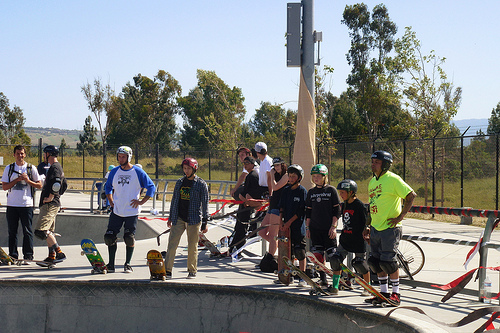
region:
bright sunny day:
[12, 7, 499, 98]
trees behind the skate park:
[7, 62, 497, 152]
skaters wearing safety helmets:
[121, 130, 431, 190]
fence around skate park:
[422, 137, 492, 195]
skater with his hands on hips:
[97, 157, 153, 227]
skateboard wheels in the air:
[85, 242, 387, 305]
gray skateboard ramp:
[23, 273, 333, 329]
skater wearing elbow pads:
[51, 175, 66, 196]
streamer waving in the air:
[425, 238, 495, 329]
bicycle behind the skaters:
[391, 232, 436, 292]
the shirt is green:
[367, 157, 417, 245]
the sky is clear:
[88, 9, 186, 51]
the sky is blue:
[52, 2, 192, 50]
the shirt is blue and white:
[90, 132, 162, 279]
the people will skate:
[72, 138, 225, 290]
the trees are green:
[341, 10, 418, 154]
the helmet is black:
[34, 137, 67, 163]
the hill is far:
[32, 121, 90, 151]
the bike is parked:
[377, 214, 439, 289]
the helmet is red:
[177, 153, 211, 187]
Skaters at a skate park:
[68, 115, 259, 313]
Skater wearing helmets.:
[86, 110, 496, 215]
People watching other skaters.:
[217, 134, 372, 279]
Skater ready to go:
[31, 117, 172, 291]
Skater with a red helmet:
[167, 142, 235, 318]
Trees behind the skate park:
[102, 87, 234, 168]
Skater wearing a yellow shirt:
[328, 116, 426, 316]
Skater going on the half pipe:
[91, 290, 175, 326]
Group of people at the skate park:
[125, 97, 395, 283]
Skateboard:
[110, 139, 183, 326]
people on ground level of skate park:
[15, 135, 450, 308]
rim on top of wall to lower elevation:
[10, 270, 401, 325]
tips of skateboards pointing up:
[75, 227, 187, 287]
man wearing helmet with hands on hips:
[90, 120, 155, 250]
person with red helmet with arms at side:
[160, 140, 211, 280]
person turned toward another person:
[15, 135, 70, 270]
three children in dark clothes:
[260, 160, 368, 295]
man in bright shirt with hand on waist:
[360, 150, 415, 310]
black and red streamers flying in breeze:
[425, 205, 495, 325]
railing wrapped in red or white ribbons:
[410, 192, 475, 262]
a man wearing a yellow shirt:
[366, 149, 416, 305]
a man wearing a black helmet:
[363, 149, 417, 307]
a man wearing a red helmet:
[167, 158, 208, 275]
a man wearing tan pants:
[165, 157, 209, 279]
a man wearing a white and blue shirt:
[95, 142, 157, 272]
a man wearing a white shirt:
[0, 143, 43, 265]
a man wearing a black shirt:
[37, 144, 69, 269]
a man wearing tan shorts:
[35, 142, 66, 268]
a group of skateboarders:
[38, 142, 416, 308]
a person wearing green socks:
[325, 177, 372, 294]